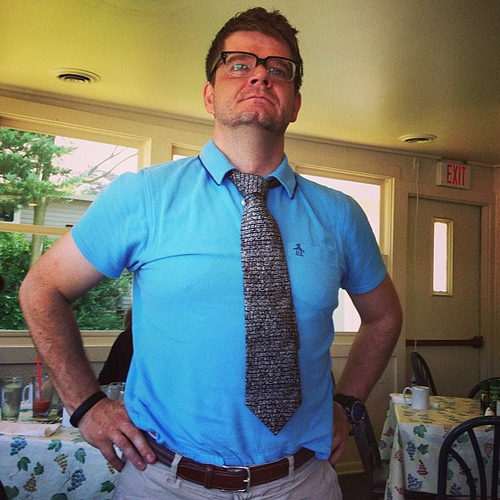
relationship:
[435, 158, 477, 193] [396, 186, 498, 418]
exit above door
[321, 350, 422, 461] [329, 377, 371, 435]
watch on wrist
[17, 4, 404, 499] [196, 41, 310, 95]
man wearing horn rimmed glasses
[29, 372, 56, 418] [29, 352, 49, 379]
glass with straw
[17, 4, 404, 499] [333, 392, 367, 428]
man wearing watch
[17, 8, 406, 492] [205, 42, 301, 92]
man wearing glasses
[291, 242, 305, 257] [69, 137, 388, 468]
logo on shirt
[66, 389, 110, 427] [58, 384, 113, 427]
band on wrist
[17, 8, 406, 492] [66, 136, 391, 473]
man wearing blue shirt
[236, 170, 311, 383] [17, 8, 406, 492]
tie on man